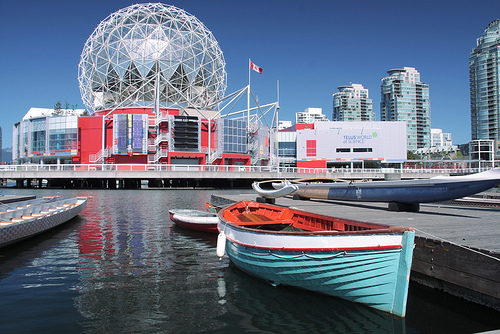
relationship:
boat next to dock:
[215, 199, 416, 318] [206, 188, 500, 308]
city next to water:
[2, 2, 500, 171] [1, 182, 500, 333]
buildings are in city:
[333, 17, 500, 145] [2, 2, 500, 171]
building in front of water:
[10, 102, 267, 165] [1, 182, 500, 333]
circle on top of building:
[77, 3, 229, 109] [10, 102, 267, 165]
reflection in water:
[70, 187, 170, 256] [1, 182, 500, 333]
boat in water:
[215, 199, 416, 318] [1, 182, 500, 333]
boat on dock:
[281, 172, 500, 212] [206, 188, 500, 308]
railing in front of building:
[1, 162, 491, 174] [10, 102, 267, 165]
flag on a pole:
[250, 60, 265, 74] [244, 58, 255, 135]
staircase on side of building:
[88, 147, 113, 164] [10, 102, 267, 165]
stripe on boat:
[217, 221, 402, 249] [215, 199, 416, 318]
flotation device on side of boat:
[216, 229, 227, 257] [215, 199, 416, 318]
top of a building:
[380, 65, 429, 94] [10, 102, 267, 165]